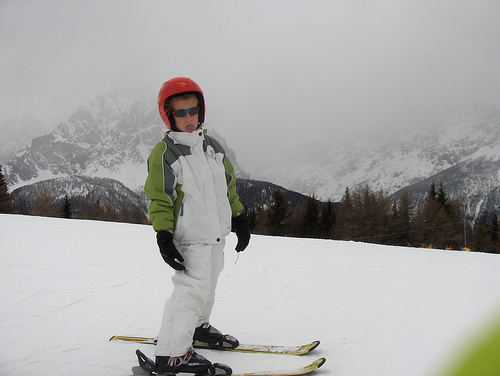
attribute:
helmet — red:
[158, 78, 207, 131]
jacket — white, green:
[151, 130, 245, 228]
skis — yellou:
[103, 329, 330, 375]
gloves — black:
[146, 231, 188, 273]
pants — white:
[150, 240, 226, 360]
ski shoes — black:
[153, 350, 220, 375]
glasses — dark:
[170, 105, 203, 118]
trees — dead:
[34, 194, 115, 214]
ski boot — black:
[152, 350, 215, 375]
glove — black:
[235, 214, 250, 252]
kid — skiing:
[142, 68, 260, 375]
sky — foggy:
[8, 3, 497, 71]